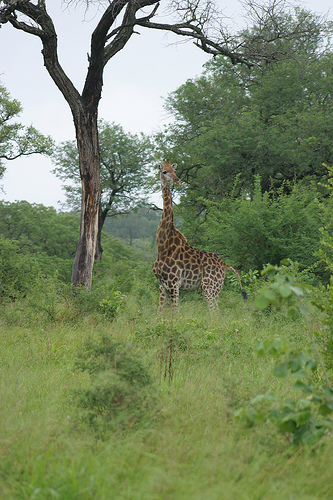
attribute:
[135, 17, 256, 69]
branch — bare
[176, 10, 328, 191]
leaves — green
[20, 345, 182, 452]
grasses — green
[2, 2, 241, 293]
tree — no leaves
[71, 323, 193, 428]
foilage — out of focus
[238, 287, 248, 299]
turf — black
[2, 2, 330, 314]
trees — background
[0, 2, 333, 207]
sky — background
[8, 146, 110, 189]
sky — hazy, blue, distant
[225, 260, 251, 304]
tail — giraffe's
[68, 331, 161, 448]
shrub — small, dark, green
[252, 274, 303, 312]
shrub — small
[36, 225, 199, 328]
foliage — small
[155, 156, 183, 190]
head — looking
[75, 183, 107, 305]
bark — striated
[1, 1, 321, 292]
tree — withered, leafless